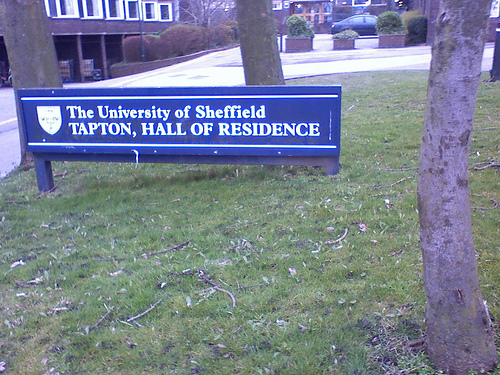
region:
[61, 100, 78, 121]
the letter T on a sign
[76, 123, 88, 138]
the letter A on a sign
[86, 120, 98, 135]
the letter P on a sign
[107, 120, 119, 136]
the letter O on a sign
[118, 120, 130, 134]
the letter N on a sign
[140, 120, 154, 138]
the letter H on a sign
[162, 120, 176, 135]
the letter L on a sign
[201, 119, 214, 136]
the letter F on a sign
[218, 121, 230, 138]
the letter R on a sign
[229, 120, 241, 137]
the letter E on a sign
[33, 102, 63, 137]
Logo of the university on the dark sign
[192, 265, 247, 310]
Small brown stick on the lawn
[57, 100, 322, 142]
White text on a long black sign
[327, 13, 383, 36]
Back of a black basic four-door car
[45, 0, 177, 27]
White framed windows that are open along the edge of the building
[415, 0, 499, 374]
Base of a brown-gray on the right side of the image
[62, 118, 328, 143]
Text on the sign in all capital letters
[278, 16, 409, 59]
Three brick square pots with hedges coming out of them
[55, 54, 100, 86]
Brown object behind black fencing underneath the building in the garage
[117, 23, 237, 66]
Brown bushes outside the dark brick brown building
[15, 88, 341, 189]
a blue sign with white writing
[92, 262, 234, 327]
broken branches on the ground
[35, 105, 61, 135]
a white logo on the sign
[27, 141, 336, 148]
a white accent stripe on the sign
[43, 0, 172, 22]
the windows are white framed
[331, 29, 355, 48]
a bush in a brick planter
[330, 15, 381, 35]
the car is parked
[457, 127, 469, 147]
a mark in the tree trunk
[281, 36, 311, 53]
the planter is red brick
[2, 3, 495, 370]
three tree trunks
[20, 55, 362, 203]
a sign in the grass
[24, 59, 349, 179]
a sign in the grass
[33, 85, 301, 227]
a sign in the grass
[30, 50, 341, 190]
a sign in the grass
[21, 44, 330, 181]
a sign in the grass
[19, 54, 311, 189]
a sign in the grass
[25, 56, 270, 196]
a sign in the grass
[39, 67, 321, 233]
a sign in the grass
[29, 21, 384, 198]
a sign in the grass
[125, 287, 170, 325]
branch on a grass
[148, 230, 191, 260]
branch on a grass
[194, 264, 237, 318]
branch on a grass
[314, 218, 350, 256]
branch on a grass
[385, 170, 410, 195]
branch on a grass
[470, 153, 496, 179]
branch on a grass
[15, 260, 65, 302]
branch on a grass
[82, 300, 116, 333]
branch on a grass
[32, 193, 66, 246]
branch on a grass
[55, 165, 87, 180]
branch on a grass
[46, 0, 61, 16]
glass window in the building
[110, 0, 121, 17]
glass window in the building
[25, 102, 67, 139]
emblem on the sign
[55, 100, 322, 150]
writing on the sign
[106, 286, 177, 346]
twig on the ground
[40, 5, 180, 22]
a row of windows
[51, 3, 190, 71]
building in the background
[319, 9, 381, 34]
car in the background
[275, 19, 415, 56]
a row of planters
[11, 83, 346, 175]
a long blue sign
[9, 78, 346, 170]
a long sign with writing on it